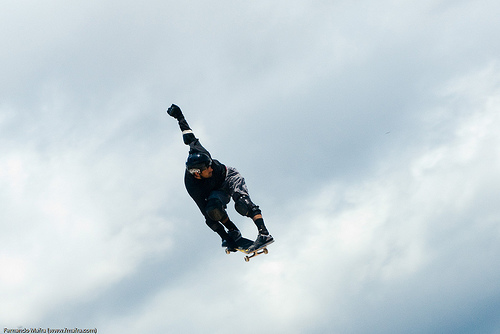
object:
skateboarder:
[166, 103, 276, 253]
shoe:
[247, 233, 275, 250]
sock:
[253, 217, 271, 235]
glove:
[167, 102, 181, 119]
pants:
[221, 168, 261, 217]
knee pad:
[234, 195, 251, 213]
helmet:
[190, 151, 211, 168]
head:
[189, 151, 214, 179]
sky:
[2, 6, 500, 333]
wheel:
[245, 254, 249, 263]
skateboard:
[223, 233, 275, 261]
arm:
[167, 103, 202, 151]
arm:
[246, 250, 268, 254]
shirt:
[183, 159, 228, 215]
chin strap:
[197, 165, 204, 181]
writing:
[189, 168, 202, 176]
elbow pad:
[181, 130, 198, 144]